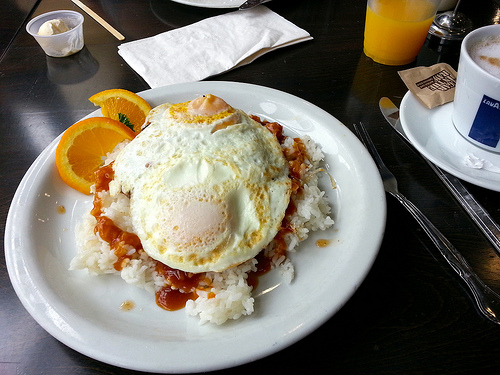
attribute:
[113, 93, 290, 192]
egg — fried, sunny side up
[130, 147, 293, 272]
egg — fried, sunny side up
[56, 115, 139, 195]
orange — sliced, cut, garnish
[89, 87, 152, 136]
orange — sliced, cut, garnish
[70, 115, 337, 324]
rice — cooked, white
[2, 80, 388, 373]
plate — white, round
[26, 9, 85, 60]
cup — plastic, small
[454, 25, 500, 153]
mug — white, blue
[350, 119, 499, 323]
fork — silver, utensil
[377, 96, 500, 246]
butter knife — silver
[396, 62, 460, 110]
sugar — in the raw, packaged, brown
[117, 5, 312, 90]
napkin — paper, white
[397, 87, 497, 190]
saucer — small